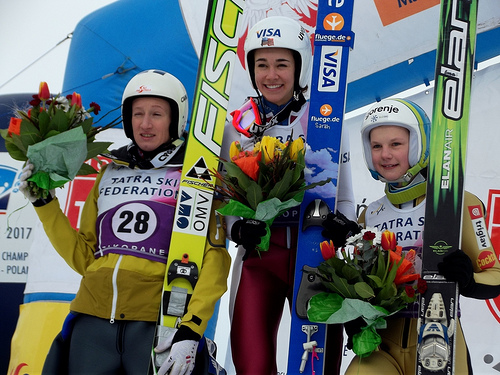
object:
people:
[16, 68, 231, 375]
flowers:
[230, 141, 240, 163]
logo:
[365, 104, 399, 122]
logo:
[136, 85, 151, 93]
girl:
[343, 98, 500, 375]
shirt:
[364, 195, 426, 248]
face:
[132, 98, 171, 152]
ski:
[147, 0, 245, 375]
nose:
[266, 66, 279, 80]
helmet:
[121, 69, 189, 139]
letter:
[112, 178, 119, 184]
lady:
[217, 16, 358, 375]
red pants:
[228, 226, 344, 375]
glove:
[153, 325, 201, 375]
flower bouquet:
[306, 227, 427, 359]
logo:
[257, 28, 281, 46]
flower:
[260, 135, 275, 165]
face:
[371, 125, 410, 180]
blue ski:
[286, 0, 354, 375]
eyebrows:
[256, 58, 267, 62]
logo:
[318, 45, 343, 92]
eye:
[134, 112, 143, 116]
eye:
[153, 113, 162, 116]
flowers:
[0, 81, 114, 199]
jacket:
[32, 139, 231, 339]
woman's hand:
[18, 159, 55, 204]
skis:
[414, 0, 477, 375]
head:
[131, 97, 171, 151]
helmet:
[244, 16, 313, 90]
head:
[254, 48, 295, 103]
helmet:
[361, 95, 431, 175]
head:
[369, 125, 409, 181]